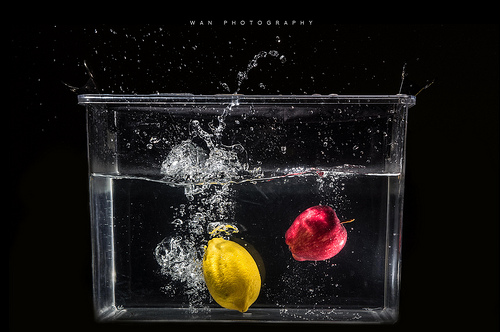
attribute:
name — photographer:
[183, 15, 313, 27]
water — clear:
[96, 166, 401, 324]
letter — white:
[182, 21, 324, 35]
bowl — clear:
[75, 91, 403, 325]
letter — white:
[238, 17, 247, 28]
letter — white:
[308, 19, 314, 25]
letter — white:
[248, 16, 253, 26]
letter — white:
[226, 17, 281, 39]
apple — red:
[281, 200, 356, 264]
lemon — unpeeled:
[191, 225, 282, 317]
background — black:
[41, 35, 472, 105]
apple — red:
[276, 194, 350, 251]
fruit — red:
[279, 208, 354, 267]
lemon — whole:
[193, 224, 272, 324]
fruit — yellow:
[194, 230, 263, 313]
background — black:
[454, 40, 482, 169]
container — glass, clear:
[65, 79, 419, 329]